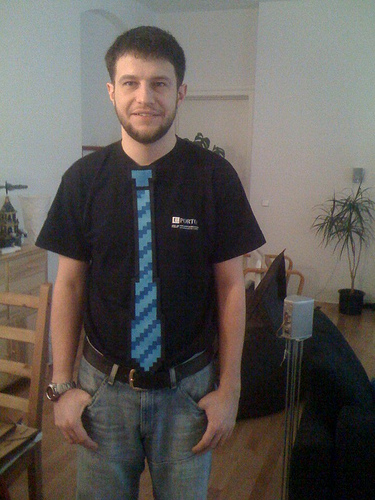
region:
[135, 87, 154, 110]
The Man's Nose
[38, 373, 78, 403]
The man's silver wristwatch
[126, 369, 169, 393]
The belt buckle of the man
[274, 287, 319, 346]
The silver portion of a speaker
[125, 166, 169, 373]
The pixelated tie of a man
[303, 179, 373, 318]
The green mini plant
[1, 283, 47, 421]
Half of a wooden Chair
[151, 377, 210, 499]
The man's left leg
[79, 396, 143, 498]
The man's right leg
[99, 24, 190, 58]
The man's hair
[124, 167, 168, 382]
A blue, pixel-patterned tie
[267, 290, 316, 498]
Gray, wired speakers on a stand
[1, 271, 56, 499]
A plane, unpadded wooden chair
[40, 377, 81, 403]
A silver strap digital watch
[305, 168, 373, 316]
A fairly tall houseplant on a wooden floor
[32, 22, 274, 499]
bearded man wearing jeans, T-shirt, and tie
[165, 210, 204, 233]
A white lettered logo on a black T-shirt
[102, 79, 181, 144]
A patchy beard of a young man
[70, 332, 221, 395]
Leather belt wrapped around jeans with a golden clip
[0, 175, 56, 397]
Tall, wooden shelf with many drawers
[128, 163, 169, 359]
blue tie on man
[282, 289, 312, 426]
tall silver electrical outlet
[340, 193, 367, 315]
green plant with black pot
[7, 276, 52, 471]
light wood dining chair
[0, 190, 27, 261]
small figurine house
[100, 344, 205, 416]
black leather belt with gold hinge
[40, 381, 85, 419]
silver large head wallet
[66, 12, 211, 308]
man smiling at camera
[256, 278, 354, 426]
black bean bag chair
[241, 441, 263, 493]
light wood hardwood floors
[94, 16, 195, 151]
The man is smiling.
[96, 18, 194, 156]
The man has hair.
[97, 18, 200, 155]
The man's hair is dark.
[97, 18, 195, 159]
The man's hair is short.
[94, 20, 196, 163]
The man has a beard.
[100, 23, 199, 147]
The man has a moustache.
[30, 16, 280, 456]
The man is wearing a watch.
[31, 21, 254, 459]
The man is wearing a belt.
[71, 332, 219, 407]
The belt is black.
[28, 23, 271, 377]
The man is wearing a shirt.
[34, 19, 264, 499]
The man is wearing jeans.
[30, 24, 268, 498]
The man's jeans are blue.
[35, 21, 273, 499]
The man's jeans are worn.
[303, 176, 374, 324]
The plant is in a pot.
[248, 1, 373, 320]
The plant is against the wall.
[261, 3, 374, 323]
The plant is tall.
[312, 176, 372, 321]
The plant container is black.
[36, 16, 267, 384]
The man is wearing a tie.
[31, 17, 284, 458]
Man's thumbs are hooked in his pockets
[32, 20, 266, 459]
Man arms are at his sides.